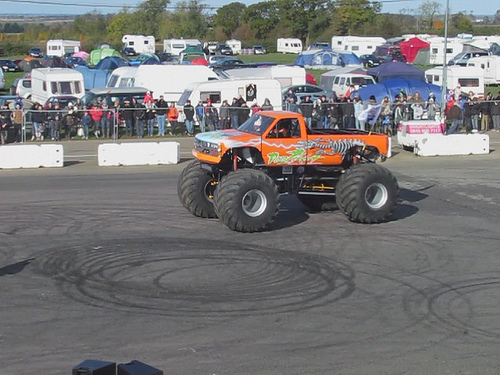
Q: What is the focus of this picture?
A: An orange monster truck.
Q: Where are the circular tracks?
A: To the left of the driver on the blacktop.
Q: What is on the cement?
A: An orange monster truck.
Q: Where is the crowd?
A: Standing by a truck.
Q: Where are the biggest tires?
A: On the orange monster truck.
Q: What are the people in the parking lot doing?
A: Spectating.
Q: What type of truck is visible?
A: A monster truck.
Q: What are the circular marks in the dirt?
A: Tire marks.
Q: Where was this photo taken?
A: At a monster truck event.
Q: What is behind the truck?
A: White barricades and people watching.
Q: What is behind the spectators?
A: RVs, cars, and tents.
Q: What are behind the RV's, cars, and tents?
A: Trees.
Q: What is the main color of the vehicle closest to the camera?
A: Orange.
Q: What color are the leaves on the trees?
A: Green.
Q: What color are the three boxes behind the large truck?
A: White.